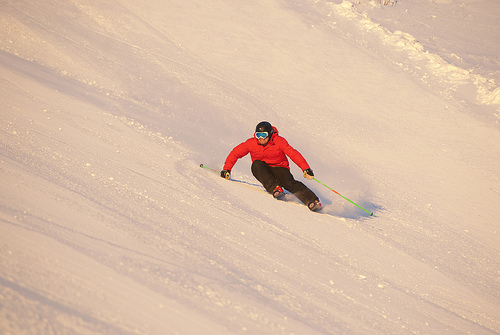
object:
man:
[221, 120, 323, 211]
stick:
[322, 178, 381, 223]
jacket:
[223, 126, 311, 173]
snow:
[0, 0, 500, 334]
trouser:
[251, 158, 320, 205]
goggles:
[255, 131, 268, 139]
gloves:
[221, 170, 231, 180]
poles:
[195, 162, 381, 219]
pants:
[251, 160, 320, 206]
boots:
[308, 199, 322, 211]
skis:
[273, 190, 326, 211]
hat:
[256, 121, 273, 134]